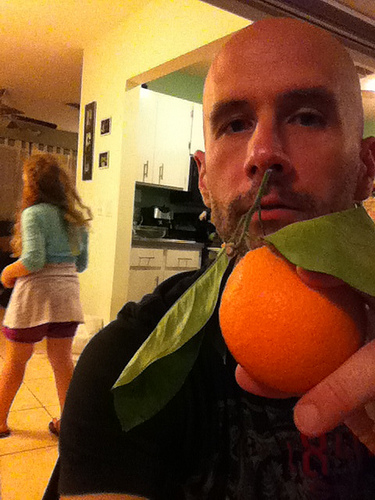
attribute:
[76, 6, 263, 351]
wall — yellow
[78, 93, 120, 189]
pictures — five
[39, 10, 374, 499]
man — looking @ camera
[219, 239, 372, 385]
orange — rough-skinned, primarily round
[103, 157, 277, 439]
leaf — green, wilting, longer than orange, not up nose, -almost- up nose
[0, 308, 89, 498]
floor — tiled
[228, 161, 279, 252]
stem — green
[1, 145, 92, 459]
woman — not wearing pink, walking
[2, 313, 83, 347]
shorts — purple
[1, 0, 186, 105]
ceiling — yellow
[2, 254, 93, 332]
shirt — grey, long, t-shirt, similar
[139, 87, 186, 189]
cabinet — white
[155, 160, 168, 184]
handle — silvertone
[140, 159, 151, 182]
handle — silvertone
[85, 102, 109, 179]
frames — three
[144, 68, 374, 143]
wall — green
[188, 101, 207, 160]
cabinet — white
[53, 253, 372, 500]
shirt — black, t-shirt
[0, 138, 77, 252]
curtain — hanging, white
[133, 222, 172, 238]
bowl — clear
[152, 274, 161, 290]
handle — silvertone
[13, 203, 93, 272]
sweater — blue, crop top sweater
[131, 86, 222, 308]
cabinets — white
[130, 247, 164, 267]
drawer — small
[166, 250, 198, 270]
drawer — small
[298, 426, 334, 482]
'8' — red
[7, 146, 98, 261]
hair — long, pretty, a little frizzy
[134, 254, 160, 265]
handle — silvertone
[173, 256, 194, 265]
handle — silvertone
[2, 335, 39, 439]
leg — left leg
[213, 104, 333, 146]
eyes — dark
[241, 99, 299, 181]
nose — uneven